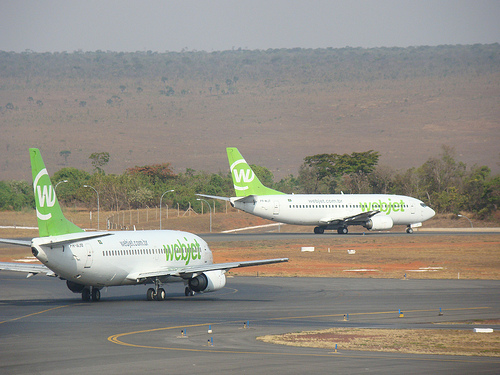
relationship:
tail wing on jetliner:
[195, 188, 260, 208] [196, 130, 456, 242]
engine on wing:
[187, 268, 226, 293] [126, 256, 288, 278]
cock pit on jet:
[413, 197, 434, 224] [0, 148, 289, 303]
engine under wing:
[196, 273, 231, 287] [166, 233, 323, 343]